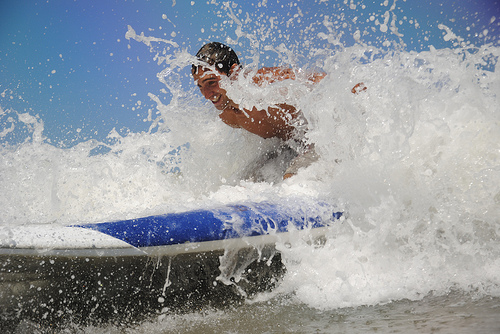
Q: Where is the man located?
A: Water.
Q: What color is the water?
A: White.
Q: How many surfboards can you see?
A: 1.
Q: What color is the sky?
A: Blue.